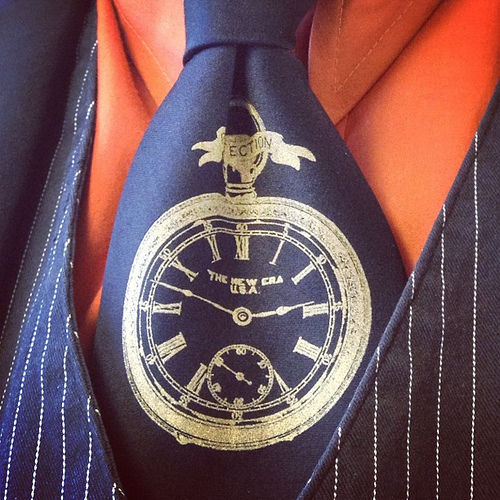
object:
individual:
[92, 0, 405, 500]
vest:
[4, 5, 499, 498]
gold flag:
[189, 125, 317, 171]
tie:
[90, 0, 408, 500]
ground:
[423, 127, 453, 164]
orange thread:
[325, 2, 419, 93]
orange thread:
[111, 0, 174, 83]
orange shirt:
[71, 0, 500, 346]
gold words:
[275, 275, 283, 284]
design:
[118, 98, 376, 454]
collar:
[307, 0, 440, 128]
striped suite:
[303, 76, 500, 499]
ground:
[350, 174, 407, 229]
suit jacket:
[2, 0, 500, 500]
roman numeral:
[153, 232, 330, 397]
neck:
[49, 4, 467, 145]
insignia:
[119, 99, 374, 453]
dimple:
[223, 39, 259, 192]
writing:
[205, 268, 285, 297]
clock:
[118, 193, 375, 453]